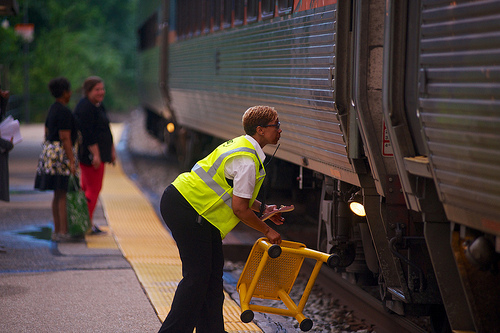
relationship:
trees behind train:
[1, 2, 142, 118] [173, 1, 496, 169]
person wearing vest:
[159, 104, 284, 331] [151, 136, 329, 296]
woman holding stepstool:
[68, 67, 116, 236] [236, 235, 328, 297]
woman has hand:
[68, 67, 116, 236] [264, 229, 284, 245]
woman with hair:
[68, 67, 116, 236] [217, 84, 289, 184]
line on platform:
[105, 151, 197, 328] [2, 123, 268, 330]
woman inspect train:
[68, 67, 116, 236] [148, 9, 498, 207]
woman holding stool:
[68, 67, 116, 236] [213, 197, 375, 332]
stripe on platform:
[89, 157, 192, 331] [2, 104, 181, 327]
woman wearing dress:
[68, 67, 116, 236] [34, 100, 81, 190]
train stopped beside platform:
[173, 1, 496, 169] [2, 123, 268, 330]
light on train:
[349, 201, 366, 216] [173, 1, 496, 169]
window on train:
[231, 4, 244, 26] [161, 9, 388, 177]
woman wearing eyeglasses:
[68, 67, 116, 236] [265, 118, 280, 129]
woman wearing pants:
[68, 67, 116, 236] [79, 162, 106, 235]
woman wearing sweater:
[68, 67, 116, 236] [73, 95, 114, 161]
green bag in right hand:
[55, 167, 101, 254] [63, 145, 78, 179]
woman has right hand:
[68, 67, 116, 236] [63, 145, 78, 179]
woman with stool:
[68, 67, 116, 236] [235, 236, 339, 331]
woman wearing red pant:
[68, 67, 116, 236] [78, 149, 113, 199]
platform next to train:
[0, 139, 262, 331] [130, 1, 498, 236]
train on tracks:
[173, 1, 496, 169] [320, 258, 421, 323]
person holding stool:
[159, 104, 284, 331] [235, 236, 339, 331]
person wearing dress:
[159, 104, 284, 331] [27, 128, 89, 198]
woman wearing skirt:
[68, 67, 116, 236] [41, 140, 77, 178]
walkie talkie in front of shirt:
[256, 143, 283, 189] [73, 95, 122, 168]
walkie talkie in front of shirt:
[256, 143, 283, 189] [168, 135, 270, 235]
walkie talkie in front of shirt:
[256, 143, 283, 189] [41, 101, 80, 144]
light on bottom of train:
[349, 201, 366, 216] [136, 10, 492, 183]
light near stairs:
[349, 201, 366, 216] [343, 100, 424, 220]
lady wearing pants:
[72, 75, 114, 235] [79, 161, 105, 231]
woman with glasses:
[68, 67, 116, 236] [265, 110, 285, 128]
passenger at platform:
[74, 75, 117, 232] [0, 120, 299, 331]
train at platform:
[173, 1, 496, 169] [0, 120, 299, 331]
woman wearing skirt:
[68, 67, 116, 236] [28, 139, 78, 196]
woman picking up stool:
[68, 67, 116, 236] [235, 236, 339, 331]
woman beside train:
[68, 67, 116, 236] [173, 1, 496, 169]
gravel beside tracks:
[323, 305, 372, 330] [330, 270, 442, 331]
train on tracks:
[130, 1, 498, 236] [274, 223, 413, 331]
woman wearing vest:
[68, 67, 116, 236] [168, 136, 268, 236]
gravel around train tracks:
[122, 152, 371, 330] [156, 142, 421, 329]